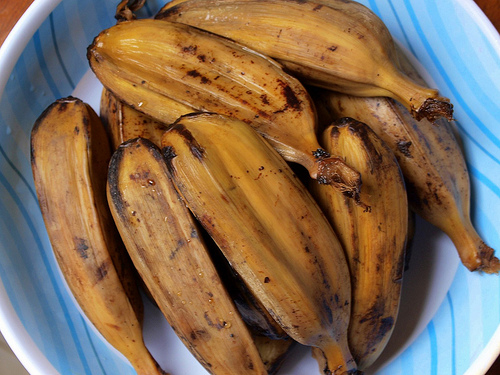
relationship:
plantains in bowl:
[75, 164, 290, 287] [2, 2, 496, 372]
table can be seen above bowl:
[4, 6, 27, 30] [2, 2, 496, 372]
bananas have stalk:
[41, 33, 490, 343] [291, 140, 361, 188]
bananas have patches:
[41, 33, 490, 343] [266, 76, 309, 116]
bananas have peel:
[41, 33, 490, 343] [111, 144, 234, 339]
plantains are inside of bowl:
[75, 164, 290, 287] [15, 276, 92, 340]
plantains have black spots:
[75, 164, 290, 287] [101, 157, 150, 220]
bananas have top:
[41, 33, 490, 343] [393, 80, 445, 115]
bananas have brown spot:
[41, 33, 490, 343] [183, 53, 246, 109]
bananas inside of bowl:
[41, 33, 490, 343] [15, 276, 92, 340]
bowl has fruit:
[15, 276, 92, 340] [258, 131, 427, 286]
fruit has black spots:
[258, 131, 427, 286] [101, 157, 150, 220]